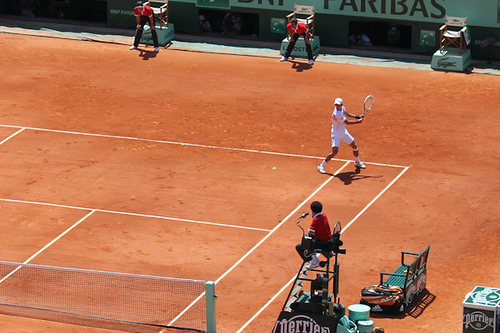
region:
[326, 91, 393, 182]
Tennis player wearing all white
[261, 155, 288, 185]
Green tennis ball in mid air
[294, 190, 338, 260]
Anouncer in red shirt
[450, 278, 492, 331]
Perrier water container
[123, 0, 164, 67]
Ball boy in red near wall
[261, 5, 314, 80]
Ball boy in red near wall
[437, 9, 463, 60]
Empty ball boy seat near wall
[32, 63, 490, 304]
Red clay tennis court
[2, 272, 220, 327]
White net stretching across court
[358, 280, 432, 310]
Black and orange Adidas bag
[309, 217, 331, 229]
Man wearing red shirt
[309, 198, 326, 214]
Man has black hair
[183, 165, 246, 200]
Brown dirt on court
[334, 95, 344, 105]
Man wearing white hat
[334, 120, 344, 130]
Man wearing white shirt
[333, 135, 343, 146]
Man wearing white shorts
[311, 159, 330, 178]
Man wearing white sneakers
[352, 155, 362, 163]
Man wearing white socks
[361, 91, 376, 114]
White tennis rack in mans hand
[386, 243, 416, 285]
Green bench in back of court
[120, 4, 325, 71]
two people bending over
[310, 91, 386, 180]
tennis player on court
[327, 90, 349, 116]
white hat on player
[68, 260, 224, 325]
net across tennis court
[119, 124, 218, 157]
white line on clay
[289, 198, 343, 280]
umpire on tsll chair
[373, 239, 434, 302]
green bench on court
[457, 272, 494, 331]
box with company logo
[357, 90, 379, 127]
racket in player's hand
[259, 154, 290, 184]
yellow tennis ball midair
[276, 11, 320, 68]
referee in a red shirt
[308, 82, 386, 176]
tennis player wearing white swinging racket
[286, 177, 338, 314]
commentator sitting on a riser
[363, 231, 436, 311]
green bench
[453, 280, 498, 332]
Perrier water advertisement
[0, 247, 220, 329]
net on the tennis court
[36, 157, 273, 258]
white lines on the tennis court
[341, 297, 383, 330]
green barrels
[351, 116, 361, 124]
red wristband worn by tennis player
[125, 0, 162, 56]
referee bent over with his hands on his knees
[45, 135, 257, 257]
Tennis court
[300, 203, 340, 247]
Referre in red shirt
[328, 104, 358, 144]
Tennis player wearing white shirt.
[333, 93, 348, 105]
Tennis player wearing white hat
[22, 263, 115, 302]
Net on tennis court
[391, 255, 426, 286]
Green chair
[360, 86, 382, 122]
Man holding tennis racket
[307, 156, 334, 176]
Man wearing white shoes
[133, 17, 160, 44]
Man wearing black pants.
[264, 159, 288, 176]
Green tennis ball